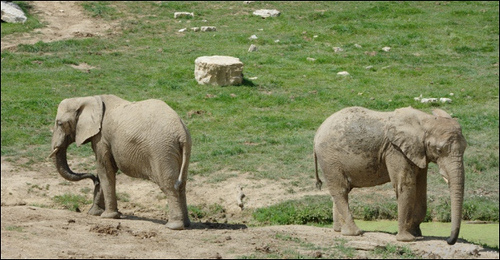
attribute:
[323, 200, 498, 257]
stream — green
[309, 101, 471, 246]
elephant — facing right, big, grey, on the right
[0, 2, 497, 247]
field — green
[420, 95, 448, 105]
rock — large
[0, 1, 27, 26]
rock — large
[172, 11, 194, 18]
rock — large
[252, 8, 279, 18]
rock — large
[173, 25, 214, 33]
rock — large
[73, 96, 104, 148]
ear — grey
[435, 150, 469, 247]
trunk — grey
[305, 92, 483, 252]
elephant — muddy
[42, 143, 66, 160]
tusks — short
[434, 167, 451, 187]
tusks — short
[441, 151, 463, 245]
trunk — wet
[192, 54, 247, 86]
rock — flat top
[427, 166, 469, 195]
tusk — white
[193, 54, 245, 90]
boulder — giant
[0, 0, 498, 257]
grass — green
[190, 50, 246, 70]
boulder top — flat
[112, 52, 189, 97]
grass — green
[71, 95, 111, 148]
ears — really big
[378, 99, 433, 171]
ears — really big